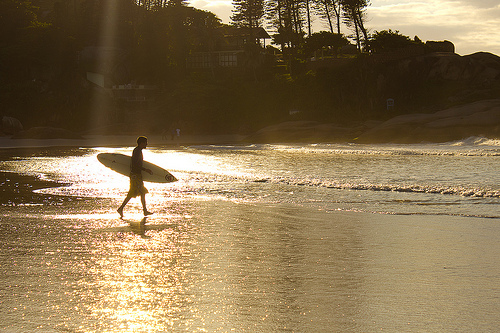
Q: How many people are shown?
A: 1.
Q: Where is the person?
A: Water.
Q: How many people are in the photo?
A: One.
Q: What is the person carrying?
A: Surfboard.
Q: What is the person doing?
A: Walking toward the ocean.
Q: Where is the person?
A: Beach.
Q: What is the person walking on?
A: Sand.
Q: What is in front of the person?
A: Ocean.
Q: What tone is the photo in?
A: Sepia.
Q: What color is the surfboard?
A: White.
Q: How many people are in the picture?
A: 1.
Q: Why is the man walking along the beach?
A: He will be going surfing.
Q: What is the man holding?
A: Surfboard.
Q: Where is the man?
A: Beach.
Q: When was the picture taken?
A: At sunset.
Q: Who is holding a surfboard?
A: A man.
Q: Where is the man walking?
A: Water's edge.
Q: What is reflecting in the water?
A: Sun.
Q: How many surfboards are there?
A: 1.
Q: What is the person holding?
A: Surfboard.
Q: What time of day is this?
A: Sunrise.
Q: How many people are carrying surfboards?
A: 1.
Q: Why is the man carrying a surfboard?
A: To use in the ocean.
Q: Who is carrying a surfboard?
A: A man.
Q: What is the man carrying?
A: A surfboard.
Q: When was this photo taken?
A: During the day.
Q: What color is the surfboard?
A: White.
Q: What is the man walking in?
A: Water.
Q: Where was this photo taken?
A: At the beach.